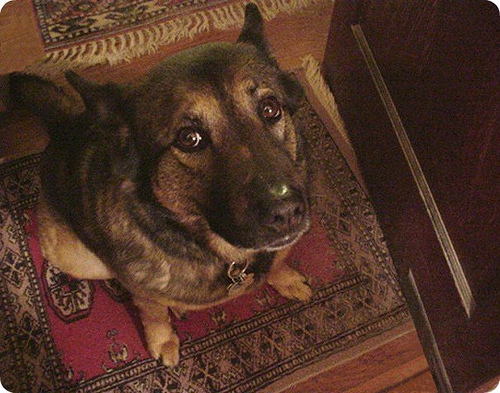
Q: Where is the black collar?
A: On dog.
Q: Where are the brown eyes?
A: On dog.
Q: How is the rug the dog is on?
A: Oriental.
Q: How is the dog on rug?
A: Sitting.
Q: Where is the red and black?
A: On rug.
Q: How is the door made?
A: Of wood.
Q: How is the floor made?
A: Of wood.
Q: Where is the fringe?
A: On rug.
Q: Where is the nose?
A: On the dog.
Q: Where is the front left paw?
A: On the dog.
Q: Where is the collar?
A: On the dog.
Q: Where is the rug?
A: On the floor.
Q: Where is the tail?
A: On the dog.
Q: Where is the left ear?
A: On the dog.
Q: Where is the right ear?
A: On the dog.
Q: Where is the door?
A: On the right.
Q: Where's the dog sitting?
A: Rug.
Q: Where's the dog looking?
A: Up.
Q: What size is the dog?
A: Medium.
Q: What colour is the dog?
A: Brown.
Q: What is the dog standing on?
A: A rug.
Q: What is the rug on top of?
A: Hardwood flooring.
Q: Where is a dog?
A: On the floor.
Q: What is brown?
A: Dog.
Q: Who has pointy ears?
A: The dog.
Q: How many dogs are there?
A: One.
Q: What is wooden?
A: Door.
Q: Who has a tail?
A: The dog.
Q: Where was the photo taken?
A: In a house.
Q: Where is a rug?
A: On floor.